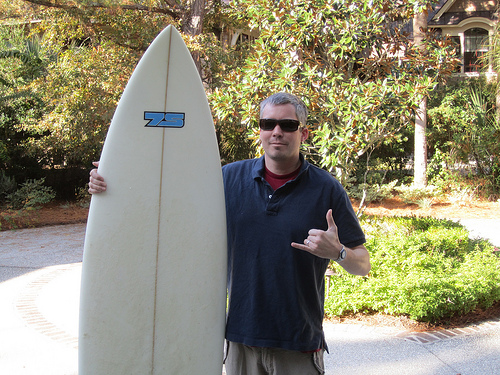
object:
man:
[87, 91, 371, 374]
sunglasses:
[258, 118, 302, 132]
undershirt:
[262, 161, 303, 191]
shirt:
[221, 153, 366, 353]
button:
[268, 193, 272, 200]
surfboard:
[80, 23, 227, 375]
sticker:
[143, 112, 186, 127]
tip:
[164, 23, 181, 34]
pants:
[223, 337, 325, 375]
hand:
[88, 161, 107, 195]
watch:
[334, 245, 346, 265]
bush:
[384, 214, 498, 322]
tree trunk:
[413, 4, 428, 189]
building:
[367, 0, 499, 83]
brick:
[405, 331, 420, 342]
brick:
[430, 327, 451, 340]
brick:
[468, 323, 482, 334]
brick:
[446, 326, 464, 336]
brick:
[486, 320, 499, 330]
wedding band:
[306, 240, 311, 246]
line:
[149, 23, 174, 375]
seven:
[143, 110, 166, 128]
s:
[158, 111, 186, 127]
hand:
[291, 207, 341, 260]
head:
[258, 92, 310, 161]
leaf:
[319, 106, 342, 131]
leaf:
[437, 103, 479, 128]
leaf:
[352, 5, 387, 29]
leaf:
[221, 87, 250, 110]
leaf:
[325, 70, 361, 102]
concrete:
[1, 216, 73, 310]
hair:
[258, 92, 310, 131]